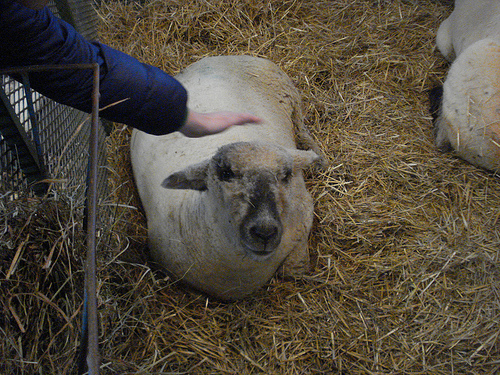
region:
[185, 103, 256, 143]
person's hand in picture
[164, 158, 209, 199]
fuzzy ear of a sheep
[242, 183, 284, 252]
black nose of sheep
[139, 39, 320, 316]
white body of sheep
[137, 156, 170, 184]
white fur of sheep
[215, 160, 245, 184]
black eye of sheep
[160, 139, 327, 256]
furry head of sheep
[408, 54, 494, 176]
back end of a sheep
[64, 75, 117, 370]
metal fence of enclosure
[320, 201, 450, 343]
yellow and brown hay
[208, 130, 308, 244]
head of a sheep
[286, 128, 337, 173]
ear of a sheep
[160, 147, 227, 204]
ear of a sheep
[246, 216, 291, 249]
nose of a sheep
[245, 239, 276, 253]
mouth of a sheep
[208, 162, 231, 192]
eye of a sheep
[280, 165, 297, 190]
eye of a sheep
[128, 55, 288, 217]
body of a sheep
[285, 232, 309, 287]
leg of a sheep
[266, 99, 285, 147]
fur of a sheep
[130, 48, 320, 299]
a sheep laying the hay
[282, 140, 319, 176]
the ear of a sheep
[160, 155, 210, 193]
the ear of a sheep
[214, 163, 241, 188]
the eye of a sheep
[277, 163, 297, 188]
the eye of a sheep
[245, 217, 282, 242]
the nose of a sheep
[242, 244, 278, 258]
the mouth of a sheep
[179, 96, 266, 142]
a hand of a person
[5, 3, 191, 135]
an arm of a person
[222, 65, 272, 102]
the wool on a sheep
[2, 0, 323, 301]
A person pets the sheep.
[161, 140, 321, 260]
The sheep has a black face.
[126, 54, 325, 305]
The sheep is mostly white.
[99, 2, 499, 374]
Straw is used for bedding.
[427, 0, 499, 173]
Another sheep lies nearby.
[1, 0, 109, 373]
A fence contains the sheep.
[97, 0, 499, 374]
The straw is a golden color.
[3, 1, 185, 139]
The person is wearing a blue coat.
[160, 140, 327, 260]
The sheep has large, dark eyes.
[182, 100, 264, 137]
The person wearing the blue coat is white.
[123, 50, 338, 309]
A sheep getting petted